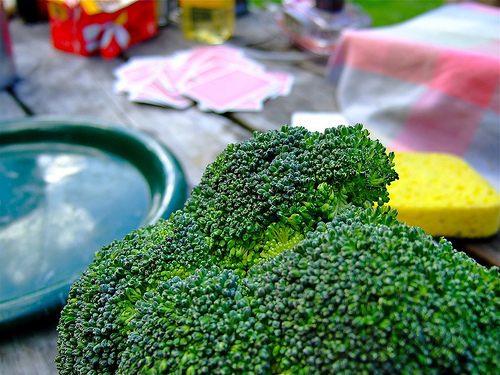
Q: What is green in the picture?
A: Broccoli.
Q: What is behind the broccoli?
A: A sponge.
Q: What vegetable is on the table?
A: Broccoli.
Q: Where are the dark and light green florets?
A: On the head of the broccoli.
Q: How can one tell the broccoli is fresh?
A: By its dark green color.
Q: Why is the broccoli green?
A: It has cholorphyll.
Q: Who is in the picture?
A: There is no person pictured.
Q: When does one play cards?
A: Whenever one has free time.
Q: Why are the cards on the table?
A: People may play cards during a picnic.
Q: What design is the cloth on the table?
A: Plaid.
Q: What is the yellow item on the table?
A: A sponge.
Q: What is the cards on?
A: A table.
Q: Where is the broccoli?
A: Beside the plate.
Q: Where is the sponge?
A: On the table.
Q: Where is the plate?
A: Beside the cards.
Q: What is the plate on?
A: The table.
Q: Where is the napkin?
A: On the table.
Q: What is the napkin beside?
A: The sponge.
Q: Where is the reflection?
A: On the plate.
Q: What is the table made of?
A: It is wood.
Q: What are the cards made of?
A: It is paper.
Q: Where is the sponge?
A: Behind the broccoli.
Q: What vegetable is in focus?
A: Broccoli.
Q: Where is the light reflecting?
A: On the plate.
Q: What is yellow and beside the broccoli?
A: A sponge.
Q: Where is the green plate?
A: Beside the broccoli.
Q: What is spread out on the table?
A: A deck of cards.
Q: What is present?
A: Vegetables.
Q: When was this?
A: Daytime.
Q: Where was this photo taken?
A: In the deck.